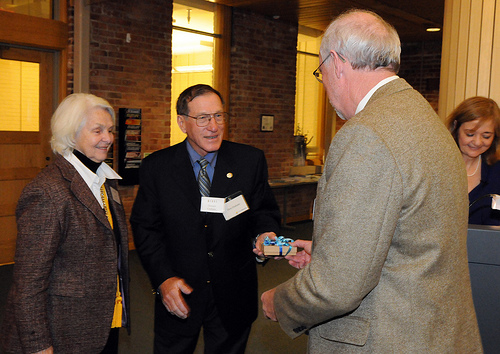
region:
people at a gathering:
[17, 18, 497, 342]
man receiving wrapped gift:
[131, 70, 296, 335]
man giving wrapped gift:
[261, 38, 496, 340]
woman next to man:
[12, 89, 141, 347]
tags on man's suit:
[183, 185, 245, 217]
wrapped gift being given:
[258, 230, 303, 267]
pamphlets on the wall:
[106, 100, 156, 187]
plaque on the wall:
[249, 103, 274, 138]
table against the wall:
[263, 150, 327, 221]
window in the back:
[293, 36, 335, 151]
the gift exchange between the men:
[129, 1, 487, 353]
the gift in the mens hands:
[258, 236, 302, 258]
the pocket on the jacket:
[317, 318, 371, 350]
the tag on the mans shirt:
[221, 186, 248, 225]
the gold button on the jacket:
[223, 171, 235, 181]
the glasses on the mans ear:
[313, 47, 356, 79]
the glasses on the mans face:
[183, 104, 228, 130]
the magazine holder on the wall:
[115, 98, 146, 183]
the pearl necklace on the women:
[463, 156, 478, 183]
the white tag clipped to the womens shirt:
[487, 189, 499, 207]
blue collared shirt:
[183, 143, 218, 199]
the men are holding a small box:
[255, 229, 310, 267]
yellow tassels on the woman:
[100, 185, 122, 326]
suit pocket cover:
[320, 316, 368, 346]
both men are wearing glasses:
[178, 33, 366, 154]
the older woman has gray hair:
[51, 95, 113, 159]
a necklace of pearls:
[467, 156, 481, 175]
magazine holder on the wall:
[118, 105, 141, 185]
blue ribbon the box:
[264, 235, 295, 260]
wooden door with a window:
[1, 48, 53, 265]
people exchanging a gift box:
[117, 0, 499, 348]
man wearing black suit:
[135, 128, 272, 350]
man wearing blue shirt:
[171, 137, 242, 213]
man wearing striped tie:
[188, 150, 223, 207]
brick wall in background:
[5, 10, 466, 262]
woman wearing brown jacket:
[0, 146, 140, 348]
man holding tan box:
[245, 225, 312, 270]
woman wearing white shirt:
[39, 131, 153, 225]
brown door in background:
[2, 9, 89, 281]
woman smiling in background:
[438, 54, 498, 260]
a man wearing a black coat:
[133, 76, 281, 351]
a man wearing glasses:
[169, 81, 228, 161]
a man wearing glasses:
[301, 9, 408, 127]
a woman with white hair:
[47, 85, 124, 167]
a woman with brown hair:
[448, 84, 495, 193]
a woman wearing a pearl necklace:
[442, 84, 499, 192]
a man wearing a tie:
[166, 80, 237, 217]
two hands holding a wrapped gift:
[252, 220, 316, 275]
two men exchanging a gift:
[133, 5, 470, 350]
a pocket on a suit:
[318, 310, 373, 350]